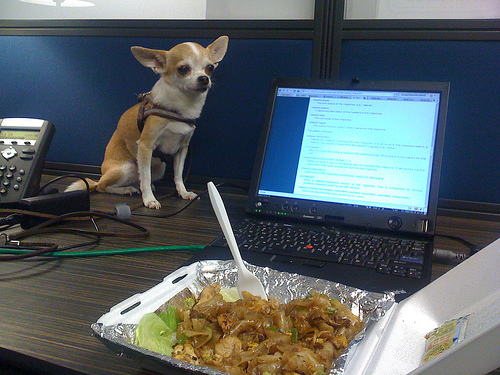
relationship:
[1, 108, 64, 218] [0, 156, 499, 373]
phone on table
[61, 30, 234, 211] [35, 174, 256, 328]
chihuaha standing on table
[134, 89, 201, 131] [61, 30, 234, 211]
harness on chihuaha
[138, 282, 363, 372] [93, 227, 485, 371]
food has container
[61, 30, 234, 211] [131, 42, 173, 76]
chihuaha has ear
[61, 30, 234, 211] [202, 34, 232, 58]
chihuaha has ear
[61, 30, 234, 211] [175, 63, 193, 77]
chihuaha has eye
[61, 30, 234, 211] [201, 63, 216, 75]
chihuaha has eye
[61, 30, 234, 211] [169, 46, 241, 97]
chihuaha has face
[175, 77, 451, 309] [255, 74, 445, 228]
computer has screen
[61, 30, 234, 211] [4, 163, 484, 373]
chihuaha on desk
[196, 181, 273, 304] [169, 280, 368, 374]
fork in food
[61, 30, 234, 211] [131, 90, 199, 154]
chihuaha wearing harness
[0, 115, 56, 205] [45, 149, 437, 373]
phone on table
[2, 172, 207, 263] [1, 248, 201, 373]
wires on table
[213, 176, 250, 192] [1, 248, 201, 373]
wires on table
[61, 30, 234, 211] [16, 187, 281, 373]
chihuaha sitting on table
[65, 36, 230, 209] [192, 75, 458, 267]
chihuaha standing near laptop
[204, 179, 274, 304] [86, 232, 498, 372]
fork in tray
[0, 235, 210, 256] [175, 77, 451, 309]
cable plugged into computer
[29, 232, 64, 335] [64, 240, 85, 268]
brown cable on green cable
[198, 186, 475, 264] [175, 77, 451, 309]
cable running behind computer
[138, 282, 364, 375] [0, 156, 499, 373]
food food on table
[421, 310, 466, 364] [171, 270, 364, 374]
packet of condiments beside food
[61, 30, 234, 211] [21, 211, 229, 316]
chihuaha on table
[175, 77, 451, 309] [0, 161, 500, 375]
computer on desk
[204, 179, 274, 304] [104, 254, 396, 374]
fork in food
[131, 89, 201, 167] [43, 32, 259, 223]
harness harness on dog